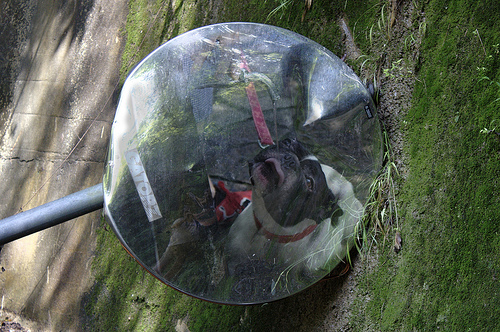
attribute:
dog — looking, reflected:
[227, 135, 364, 278]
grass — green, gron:
[269, 130, 399, 299]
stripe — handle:
[240, 54, 278, 145]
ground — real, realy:
[0, 2, 499, 332]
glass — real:
[104, 22, 385, 308]